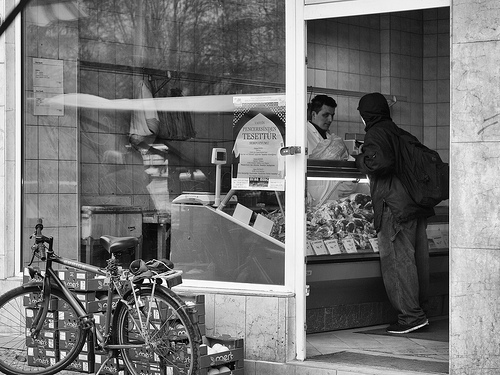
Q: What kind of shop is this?
A: Butcher.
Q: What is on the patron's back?
A: Backpack.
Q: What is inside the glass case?
A: Meat.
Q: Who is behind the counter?
A: A butcher.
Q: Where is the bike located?
A: In front of the shop.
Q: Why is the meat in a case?
A: To keep is cold.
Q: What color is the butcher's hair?
A: Black.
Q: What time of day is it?
A: Daytime.